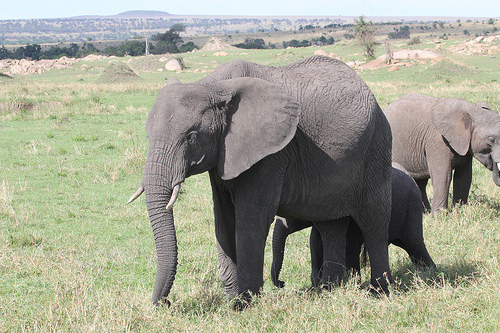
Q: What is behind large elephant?
A: Baby elephant.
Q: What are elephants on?
A: Lush green grass.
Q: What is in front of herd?
A: Big grey adult elephant.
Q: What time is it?
A: Afternoon.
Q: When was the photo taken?
A: During the daytime.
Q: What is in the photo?
A: Elephants.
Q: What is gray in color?
A: The elephants.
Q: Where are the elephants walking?
A: Grassy flat land.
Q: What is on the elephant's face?
A: Tusks.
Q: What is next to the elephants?
A: Grass.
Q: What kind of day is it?
A: Sunny.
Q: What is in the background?
A: Many trees.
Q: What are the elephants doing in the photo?
A: Walking.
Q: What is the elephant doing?
A: Standing.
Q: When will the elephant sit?
A: When he wants.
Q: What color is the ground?
A: Green.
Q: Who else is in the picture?
A: 2 more elephants.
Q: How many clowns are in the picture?
A: None.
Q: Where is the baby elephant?
A: Under the bigger one.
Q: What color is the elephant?
A: Gray.